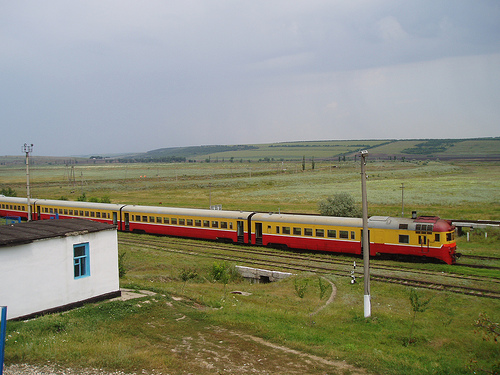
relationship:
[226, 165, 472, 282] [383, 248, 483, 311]
train on tracks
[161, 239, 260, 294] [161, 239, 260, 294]
grass of grass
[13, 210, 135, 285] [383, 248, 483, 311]
buliding by tracks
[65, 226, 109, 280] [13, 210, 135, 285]
window on buliding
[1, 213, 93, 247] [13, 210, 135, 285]
roof of buliding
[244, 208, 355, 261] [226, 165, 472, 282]
car on train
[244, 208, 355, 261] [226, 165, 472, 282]
car of train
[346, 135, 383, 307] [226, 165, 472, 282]
pole by train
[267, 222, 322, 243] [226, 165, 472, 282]
window on train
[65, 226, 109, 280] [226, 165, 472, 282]
window by train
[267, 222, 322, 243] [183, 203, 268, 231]
window on side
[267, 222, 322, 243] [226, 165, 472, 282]
window by train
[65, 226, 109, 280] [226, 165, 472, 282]
window on train